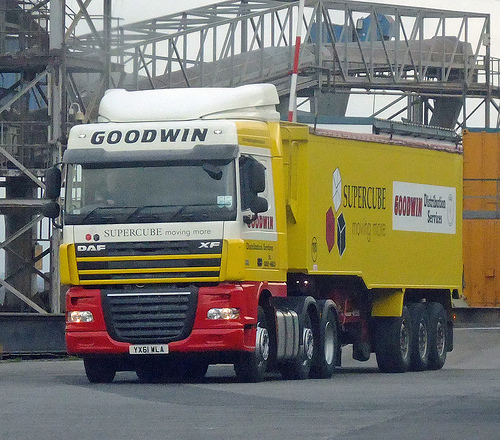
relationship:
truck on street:
[50, 53, 486, 323] [55, 351, 423, 423]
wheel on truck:
[265, 286, 340, 416] [50, 53, 486, 323]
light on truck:
[178, 292, 243, 350] [50, 53, 486, 323]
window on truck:
[222, 159, 270, 254] [50, 53, 486, 323]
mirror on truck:
[220, 157, 288, 225] [45, 78, 447, 382]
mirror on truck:
[220, 157, 288, 225] [50, 53, 486, 323]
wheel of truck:
[265, 286, 340, 416] [50, 53, 486, 323]